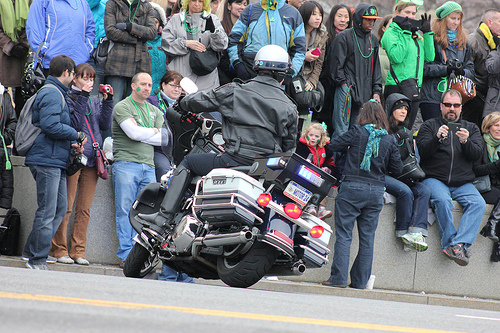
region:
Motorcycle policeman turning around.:
[136, 16, 353, 304]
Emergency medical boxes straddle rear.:
[191, 156, 345, 278]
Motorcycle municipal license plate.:
[272, 174, 322, 211]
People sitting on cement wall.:
[381, 91, 499, 241]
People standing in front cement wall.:
[22, 51, 159, 266]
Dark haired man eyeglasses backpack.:
[17, 56, 71, 238]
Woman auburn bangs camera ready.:
[76, 65, 110, 267]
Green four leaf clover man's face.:
[114, 68, 161, 138]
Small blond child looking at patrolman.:
[294, 122, 342, 221]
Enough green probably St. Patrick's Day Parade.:
[109, 2, 499, 158]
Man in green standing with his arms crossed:
[110, 72, 170, 269]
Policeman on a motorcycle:
[120, 43, 337, 290]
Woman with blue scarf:
[322, 100, 406, 290]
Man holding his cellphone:
[416, 88, 488, 264]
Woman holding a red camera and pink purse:
[47, 62, 113, 266]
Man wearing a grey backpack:
[11, 54, 87, 271]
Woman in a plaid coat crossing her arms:
[102, 0, 154, 141]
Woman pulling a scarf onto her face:
[380, 0, 436, 131]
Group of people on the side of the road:
[1, 0, 498, 291]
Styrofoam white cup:
[364, 273, 378, 290]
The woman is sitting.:
[376, 86, 436, 258]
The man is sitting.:
[415, 80, 492, 270]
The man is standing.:
[12, 51, 89, 278]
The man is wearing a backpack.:
[12, 51, 87, 274]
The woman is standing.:
[46, 53, 118, 269]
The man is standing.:
[106, 68, 174, 275]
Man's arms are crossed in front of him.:
[102, 70, 174, 275]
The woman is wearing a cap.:
[423, 0, 470, 88]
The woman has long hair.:
[426, 0, 473, 72]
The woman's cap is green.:
[431, 0, 470, 79]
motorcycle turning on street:
[129, 35, 336, 292]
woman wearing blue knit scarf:
[331, 88, 401, 291]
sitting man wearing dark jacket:
[419, 84, 494, 267]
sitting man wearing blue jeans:
[425, 84, 490, 269]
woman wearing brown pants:
[56, 63, 103, 266]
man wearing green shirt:
[112, 66, 170, 176]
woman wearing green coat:
[387, 4, 437, 90]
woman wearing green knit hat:
[432, 0, 469, 58]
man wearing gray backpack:
[11, 52, 73, 269]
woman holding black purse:
[161, 2, 229, 77]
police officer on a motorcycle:
[152, 42, 337, 271]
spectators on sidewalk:
[20, 14, 485, 213]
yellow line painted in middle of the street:
[50, 293, 157, 319]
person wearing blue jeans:
[19, 151, 63, 264]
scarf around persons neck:
[353, 120, 388, 169]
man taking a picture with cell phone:
[434, 92, 471, 144]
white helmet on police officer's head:
[247, 38, 304, 90]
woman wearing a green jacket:
[384, 0, 439, 80]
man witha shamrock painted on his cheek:
[130, 70, 156, 98]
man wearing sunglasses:
[427, 83, 483, 136]